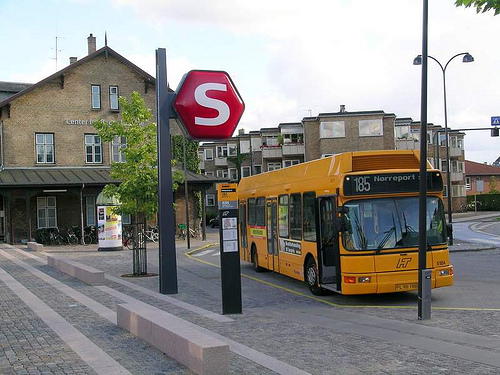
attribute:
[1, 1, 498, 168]
sky — overcast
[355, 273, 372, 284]
headlight — white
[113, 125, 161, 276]
tree — little, green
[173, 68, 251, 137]
sign — red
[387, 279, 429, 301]
license plate — yellow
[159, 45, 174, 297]
pole — black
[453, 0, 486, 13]
leaves — green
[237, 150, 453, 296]
bus — yellow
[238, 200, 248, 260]
door — double